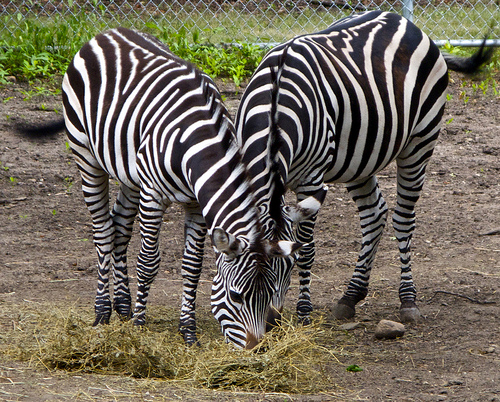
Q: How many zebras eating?
A: Two.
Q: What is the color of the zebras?
A: Black and white.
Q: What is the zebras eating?
A: Grass.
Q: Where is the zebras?
A: Inside the fence.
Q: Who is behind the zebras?
A: No one.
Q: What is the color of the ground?
A: Brown.